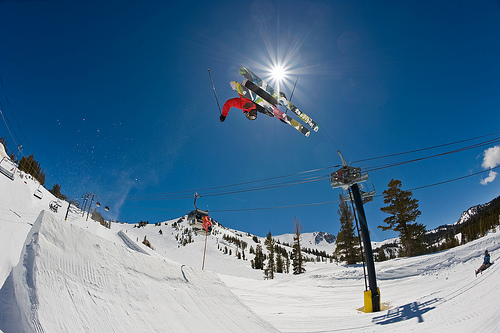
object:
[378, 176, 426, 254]
tree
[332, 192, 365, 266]
tree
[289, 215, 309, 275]
tree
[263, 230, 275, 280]
tree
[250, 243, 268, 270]
tree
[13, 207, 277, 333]
half pipe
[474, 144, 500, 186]
cloud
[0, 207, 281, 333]
ski ramp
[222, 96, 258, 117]
jacket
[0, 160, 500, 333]
snow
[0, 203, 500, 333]
ground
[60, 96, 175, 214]
cloud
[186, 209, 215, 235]
chair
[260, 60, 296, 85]
sun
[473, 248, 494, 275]
person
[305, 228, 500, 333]
slope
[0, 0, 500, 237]
sky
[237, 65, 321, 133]
board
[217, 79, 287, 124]
person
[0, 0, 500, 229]
blue sky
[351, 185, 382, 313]
pole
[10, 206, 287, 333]
facility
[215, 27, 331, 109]
lens flare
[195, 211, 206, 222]
person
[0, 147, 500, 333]
resort area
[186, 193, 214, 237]
ski lift